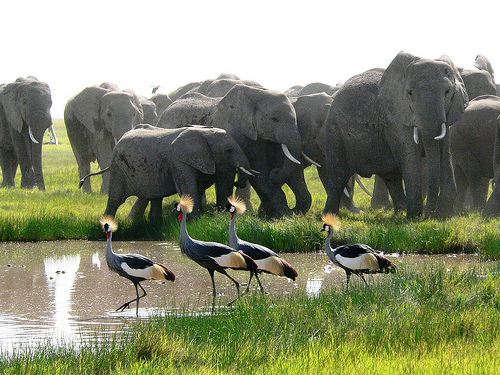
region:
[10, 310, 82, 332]
Ripples on the water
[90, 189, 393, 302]
Birds walking in the water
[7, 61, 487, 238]
Group of elephants on the grass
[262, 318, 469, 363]
Tall yellow and green grass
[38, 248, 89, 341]
Reflection from sun on the water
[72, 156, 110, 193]
Elephant tail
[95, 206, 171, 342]
Bird with one leg in water and one in the air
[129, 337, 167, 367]
Stone in grass by water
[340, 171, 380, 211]
Elephant tusks almost touching ground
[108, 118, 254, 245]
Smallest elephant walking by water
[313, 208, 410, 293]
black and white right hand bird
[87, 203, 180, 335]
black and white lead bird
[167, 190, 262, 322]
black and white second bird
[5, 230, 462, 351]
murky brown pond water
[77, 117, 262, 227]
baby elephant near mother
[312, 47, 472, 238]
large gray elephant looking forward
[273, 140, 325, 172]
long white elephant tusks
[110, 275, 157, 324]
long spindly bird legs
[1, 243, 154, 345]
reflection of elephants in water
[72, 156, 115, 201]
thin gray elephant tail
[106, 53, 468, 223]
herd of walking elephants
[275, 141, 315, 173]
white tusks on elephant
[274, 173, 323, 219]
walking legs of elephant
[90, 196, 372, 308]
four birds walking in water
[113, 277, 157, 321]
bent leg of bird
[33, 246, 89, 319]
light reflection on water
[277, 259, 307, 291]
tail feather on bird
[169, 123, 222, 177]
ear on young elephant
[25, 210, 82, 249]
green grass above water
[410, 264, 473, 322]
tall green grass on ground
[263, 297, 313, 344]
part of a shore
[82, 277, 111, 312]
part of a water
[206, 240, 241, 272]
edge of a wing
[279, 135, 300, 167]
tip of a tusk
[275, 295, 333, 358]
part of some grass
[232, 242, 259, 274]
edge of a tail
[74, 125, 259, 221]
a standing grey elephant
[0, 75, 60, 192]
a standing grey elephant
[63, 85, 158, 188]
a standing grey elephant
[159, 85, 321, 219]
a standing grey elephant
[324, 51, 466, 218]
a standing grey elephant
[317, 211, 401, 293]
a tall feathered bird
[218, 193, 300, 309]
a large bird in water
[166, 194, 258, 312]
a large bird in water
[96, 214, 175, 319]
a large bird in water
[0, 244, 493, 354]
a small body of water